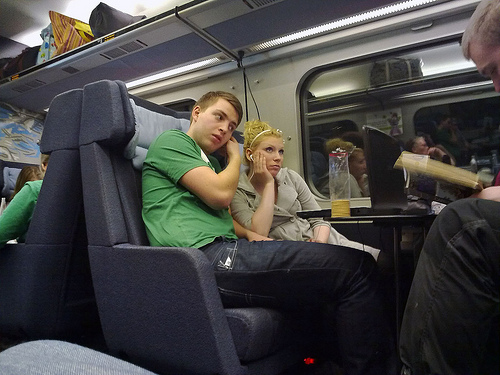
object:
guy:
[139, 90, 391, 375]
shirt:
[141, 127, 239, 250]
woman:
[229, 119, 394, 286]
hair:
[243, 120, 285, 150]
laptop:
[295, 125, 407, 218]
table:
[321, 213, 441, 375]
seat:
[76, 76, 300, 375]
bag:
[86, 2, 150, 39]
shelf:
[0, 0, 405, 107]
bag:
[47, 9, 94, 54]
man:
[396, 0, 499, 375]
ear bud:
[250, 154, 254, 160]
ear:
[245, 148, 254, 163]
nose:
[219, 121, 229, 134]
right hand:
[249, 150, 275, 186]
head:
[242, 120, 284, 178]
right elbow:
[201, 180, 234, 210]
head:
[188, 89, 243, 153]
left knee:
[421, 197, 499, 263]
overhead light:
[115, 1, 442, 90]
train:
[0, 0, 499, 374]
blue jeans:
[196, 235, 384, 374]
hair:
[190, 91, 243, 127]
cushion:
[126, 99, 195, 168]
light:
[303, 357, 315, 364]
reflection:
[305, 120, 366, 199]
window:
[295, 30, 500, 203]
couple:
[140, 88, 387, 375]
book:
[392, 150, 487, 193]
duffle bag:
[367, 55, 424, 87]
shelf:
[306, 66, 493, 109]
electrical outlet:
[232, 48, 248, 58]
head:
[456, 0, 500, 99]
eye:
[488, 64, 499, 80]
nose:
[492, 81, 500, 94]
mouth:
[210, 133, 222, 143]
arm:
[154, 132, 243, 210]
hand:
[225, 135, 241, 158]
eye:
[279, 148, 284, 154]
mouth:
[269, 163, 280, 169]